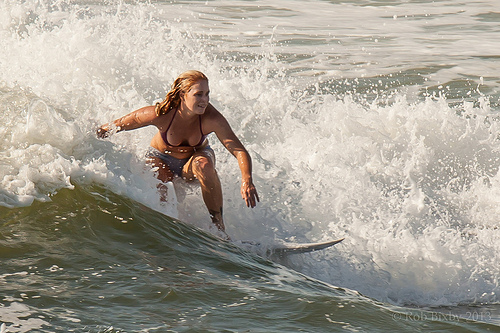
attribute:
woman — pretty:
[106, 83, 281, 242]